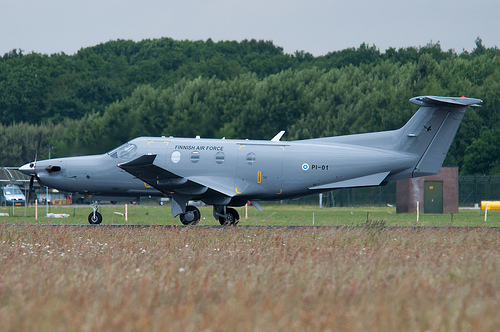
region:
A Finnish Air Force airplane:
[19, 92, 484, 223]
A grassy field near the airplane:
[3, 203, 493, 220]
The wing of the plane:
[116, 147, 157, 174]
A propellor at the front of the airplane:
[21, 132, 46, 211]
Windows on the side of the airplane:
[169, 150, 229, 165]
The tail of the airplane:
[340, 95, 479, 165]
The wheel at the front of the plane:
[88, 197, 102, 224]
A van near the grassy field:
[3, 184, 25, 204]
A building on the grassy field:
[396, 165, 459, 211]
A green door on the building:
[421, 179, 444, 214]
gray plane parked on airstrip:
[11, 88, 497, 228]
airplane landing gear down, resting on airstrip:
[76, 196, 263, 232]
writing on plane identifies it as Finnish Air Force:
[164, 136, 239, 156]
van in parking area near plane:
[2, 180, 29, 210]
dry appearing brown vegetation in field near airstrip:
[6, 223, 491, 315]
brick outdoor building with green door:
[389, 162, 470, 211]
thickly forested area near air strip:
[12, 90, 400, 135]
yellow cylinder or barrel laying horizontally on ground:
[475, 196, 498, 213]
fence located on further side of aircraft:
[0, 171, 499, 216]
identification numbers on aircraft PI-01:
[299, 161, 334, 173]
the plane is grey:
[25, 75, 473, 242]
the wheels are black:
[47, 186, 248, 246]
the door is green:
[416, 172, 452, 216]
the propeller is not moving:
[7, 125, 53, 197]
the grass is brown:
[227, 222, 469, 320]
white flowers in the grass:
[1, 221, 114, 269]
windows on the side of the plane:
[157, 143, 272, 174]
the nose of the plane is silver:
[6, 149, 36, 179]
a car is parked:
[0, 183, 50, 215]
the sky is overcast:
[17, 0, 477, 64]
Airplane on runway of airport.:
[14, 88, 490, 227]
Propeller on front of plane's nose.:
[7, 128, 42, 213]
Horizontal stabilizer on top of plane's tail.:
[407, 93, 487, 110]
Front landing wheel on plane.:
[80, 203, 108, 228]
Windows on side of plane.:
[169, 148, 233, 168]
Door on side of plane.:
[231, 138, 290, 197]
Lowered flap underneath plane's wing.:
[167, 191, 194, 218]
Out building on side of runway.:
[391, 159, 466, 216]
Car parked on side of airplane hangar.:
[1, 181, 26, 206]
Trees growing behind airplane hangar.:
[61, 36, 347, 130]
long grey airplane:
[17, 92, 485, 225]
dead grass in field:
[16, 228, 498, 330]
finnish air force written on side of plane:
[171, 142, 225, 152]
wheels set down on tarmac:
[84, 205, 242, 227]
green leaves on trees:
[4, 35, 497, 171]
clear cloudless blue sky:
[2, 4, 496, 56]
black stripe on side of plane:
[115, 152, 231, 202]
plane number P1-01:
[310, 160, 330, 172]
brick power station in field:
[394, 163, 461, 213]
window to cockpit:
[102, 142, 140, 159]